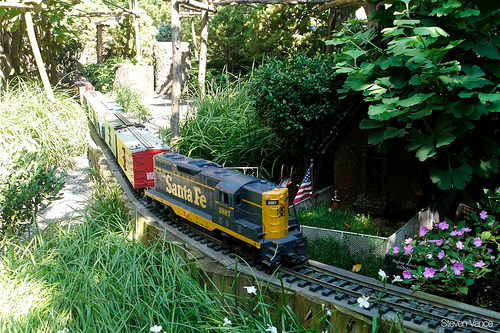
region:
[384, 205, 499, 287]
flowers are pink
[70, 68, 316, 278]
train is a toy train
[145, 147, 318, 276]
Then engine is green and yellow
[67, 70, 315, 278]
Train has several cars attached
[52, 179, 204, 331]
grass blades are long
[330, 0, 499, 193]
bush is a bright green color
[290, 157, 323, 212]
american flag is small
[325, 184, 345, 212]
figure is of a man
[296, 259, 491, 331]
tracks are on wood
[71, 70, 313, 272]
train is not a real train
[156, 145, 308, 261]
a yellow toy train car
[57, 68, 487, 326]
a toy train set in a toy forest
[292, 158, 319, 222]
an american flag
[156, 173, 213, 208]
text on the side of a train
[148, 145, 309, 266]
a yellow and black train car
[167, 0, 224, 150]
a wooden telephone pole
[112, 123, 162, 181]
a red train car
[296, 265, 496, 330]
a black train track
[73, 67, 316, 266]
a long train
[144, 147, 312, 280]
a model train engine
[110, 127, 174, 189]
a model train car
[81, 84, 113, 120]
a model train car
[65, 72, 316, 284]
a model train on a track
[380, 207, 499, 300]
pink flowers growing in the ground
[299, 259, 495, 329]
model railroad tracks on the ground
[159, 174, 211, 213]
a santa fe train logo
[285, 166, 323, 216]
a small american flag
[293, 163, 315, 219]
small american flag in the ground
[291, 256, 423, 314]
model train track on top of the bricks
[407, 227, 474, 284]
pink flowers by the tracks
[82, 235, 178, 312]
tall grass growing by the tracks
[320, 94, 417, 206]
small house hidden in the bushes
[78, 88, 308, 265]
model train on the tracks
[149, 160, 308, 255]
grey and yellow engine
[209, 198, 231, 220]
numbers on the side of the engine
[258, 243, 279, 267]
steps going up the engine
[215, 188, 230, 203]
windows in the side of the train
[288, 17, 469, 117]
Green bushes to the right of toy train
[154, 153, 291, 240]
Yellow and grey design of train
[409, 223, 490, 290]
Flowers near a train track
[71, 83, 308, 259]
A toy train on the train tracks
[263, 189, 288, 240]
Front of a train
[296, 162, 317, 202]
A American flag next to a train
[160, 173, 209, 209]
"Santa Fe" written on side of the train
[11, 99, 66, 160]
Grass in the sunlight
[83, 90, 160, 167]
Middle part of a train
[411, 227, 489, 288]
Pink flowers in a bush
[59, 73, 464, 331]
a train on tracks